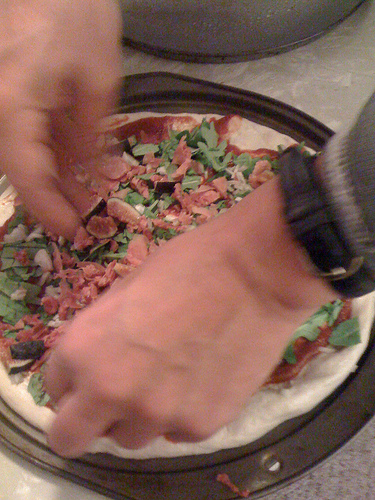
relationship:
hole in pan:
[264, 458, 280, 471] [1, 71, 372, 499]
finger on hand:
[48, 391, 114, 462] [45, 154, 345, 461]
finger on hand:
[110, 419, 160, 449] [45, 154, 345, 461]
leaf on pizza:
[198, 121, 228, 170] [0, 113, 375, 461]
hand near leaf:
[45, 154, 345, 461] [198, 121, 228, 170]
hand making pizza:
[45, 154, 345, 461] [0, 113, 375, 461]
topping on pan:
[216, 473, 250, 498] [1, 71, 372, 499]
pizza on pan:
[0, 113, 375, 461] [1, 71, 372, 499]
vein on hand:
[124, 335, 197, 373] [45, 154, 345, 461]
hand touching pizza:
[45, 154, 345, 461] [0, 113, 375, 461]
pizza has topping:
[0, 113, 375, 461] [106, 198, 140, 225]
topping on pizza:
[106, 198, 140, 225] [0, 113, 375, 461]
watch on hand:
[277, 146, 375, 299] [45, 154, 345, 461]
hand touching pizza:
[0, 1, 124, 243] [0, 113, 375, 461]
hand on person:
[45, 154, 345, 461] [4, 5, 372, 459]